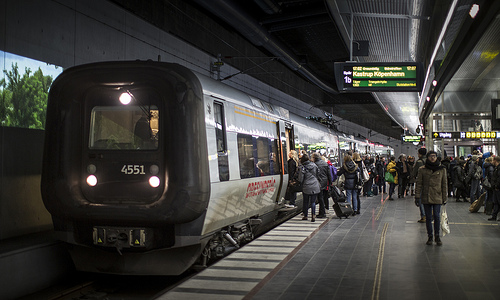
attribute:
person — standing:
[411, 141, 458, 256]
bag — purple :
[327, 187, 353, 224]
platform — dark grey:
[231, 209, 499, 297]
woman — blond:
[283, 148, 298, 207]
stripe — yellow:
[364, 216, 392, 296]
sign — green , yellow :
[340, 60, 420, 94]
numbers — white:
[120, 164, 146, 175]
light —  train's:
[117, 91, 134, 108]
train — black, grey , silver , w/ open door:
[37, 55, 394, 280]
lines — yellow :
[368, 222, 389, 299]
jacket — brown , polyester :
[422, 159, 456, 211]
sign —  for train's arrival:
[336, 58, 439, 92]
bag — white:
[430, 197, 472, 248]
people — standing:
[324, 152, 498, 229]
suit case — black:
[334, 196, 354, 225]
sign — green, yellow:
[334, 60, 421, 92]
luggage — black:
[330, 181, 362, 216]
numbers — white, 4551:
[122, 163, 147, 178]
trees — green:
[0, 58, 49, 127]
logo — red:
[230, 179, 283, 205]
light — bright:
[93, 76, 175, 119]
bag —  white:
[440, 203, 450, 234]